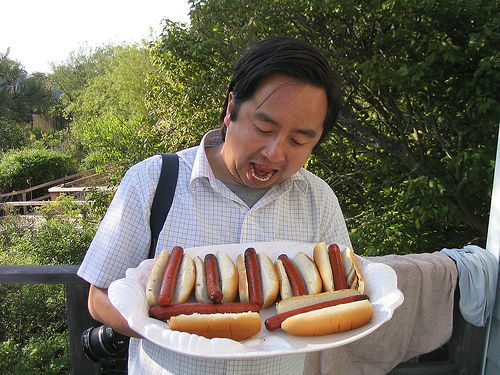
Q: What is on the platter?
A: Hot dogs.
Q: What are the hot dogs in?
A: Bun.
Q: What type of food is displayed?
A: Hot dogs on a bun?.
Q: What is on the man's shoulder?
A: Camera.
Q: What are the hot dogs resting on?
A: Platter.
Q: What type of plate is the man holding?
A: Platter.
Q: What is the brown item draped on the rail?
A: Towel.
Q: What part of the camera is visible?
A: Lens.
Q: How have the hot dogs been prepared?
A: Grilled.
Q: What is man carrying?
A: Camera.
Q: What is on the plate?
A: Hot dogs.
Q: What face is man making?
A: Funny.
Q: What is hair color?
A: Black.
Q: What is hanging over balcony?
A: Clothing.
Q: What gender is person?
A: Male.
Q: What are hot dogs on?
A: Serving tray.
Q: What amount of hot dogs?
A: Seven.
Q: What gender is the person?
A: Male.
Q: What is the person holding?
A: A plate.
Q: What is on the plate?
A: Hot Dogs.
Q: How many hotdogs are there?
A: 7.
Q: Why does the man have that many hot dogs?
A: Hungry.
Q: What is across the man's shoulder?
A: Camera.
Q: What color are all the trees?
A: Green.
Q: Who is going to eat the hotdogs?
A: The man.